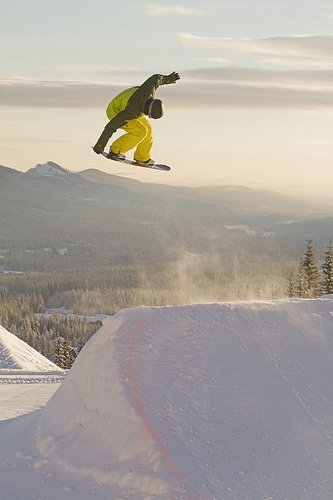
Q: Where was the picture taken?
A: It was taken at the forest.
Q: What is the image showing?
A: It is showing a forest.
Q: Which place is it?
A: It is a forest.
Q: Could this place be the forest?
A: Yes, it is the forest.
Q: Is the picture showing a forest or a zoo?
A: It is showing a forest.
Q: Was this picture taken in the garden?
A: No, the picture was taken in the forest.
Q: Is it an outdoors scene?
A: Yes, it is outdoors.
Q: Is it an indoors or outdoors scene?
A: It is outdoors.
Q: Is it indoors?
A: No, it is outdoors.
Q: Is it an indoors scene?
A: No, it is outdoors.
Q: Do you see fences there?
A: No, there are no fences.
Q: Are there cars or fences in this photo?
A: No, there are no fences or cars.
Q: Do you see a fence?
A: No, there are no fences.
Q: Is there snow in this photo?
A: Yes, there is snow.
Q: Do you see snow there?
A: Yes, there is snow.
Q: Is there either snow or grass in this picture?
A: Yes, there is snow.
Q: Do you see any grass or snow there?
A: Yes, there is snow.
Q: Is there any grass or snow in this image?
A: Yes, there is snow.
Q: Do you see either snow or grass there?
A: Yes, there is snow.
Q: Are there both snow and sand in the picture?
A: No, there is snow but no sand.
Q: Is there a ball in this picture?
A: No, there are no balls.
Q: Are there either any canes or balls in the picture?
A: No, there are no balls or canes.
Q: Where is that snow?
A: The snow is on the ground.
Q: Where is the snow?
A: The snow is on the ground.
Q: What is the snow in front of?
A: The snow is in front of the trees.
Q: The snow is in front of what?
A: The snow is in front of the trees.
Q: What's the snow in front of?
A: The snow is in front of the trees.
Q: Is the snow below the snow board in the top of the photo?
A: Yes, the snow is below the snow board.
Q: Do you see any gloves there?
A: Yes, there are gloves.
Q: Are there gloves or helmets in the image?
A: Yes, there are gloves.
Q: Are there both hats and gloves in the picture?
A: Yes, there are both gloves and a hat.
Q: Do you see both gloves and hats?
A: Yes, there are both gloves and a hat.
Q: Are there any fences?
A: No, there are no fences.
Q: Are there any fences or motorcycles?
A: No, there are no fences or motorcycles.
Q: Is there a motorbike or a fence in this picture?
A: No, there are no fences or motorcycles.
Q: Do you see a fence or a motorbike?
A: No, there are no fences or motorcycles.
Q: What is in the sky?
A: The clouds are in the sky.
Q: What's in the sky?
A: The clouds are in the sky.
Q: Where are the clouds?
A: The clouds are in the sky.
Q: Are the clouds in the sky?
A: Yes, the clouds are in the sky.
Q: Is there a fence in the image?
A: No, there are no fences.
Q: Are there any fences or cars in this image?
A: No, there are no fences or cars.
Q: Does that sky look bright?
A: Yes, the sky is bright.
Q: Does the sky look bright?
A: Yes, the sky is bright.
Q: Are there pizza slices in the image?
A: No, there are no pizza slices.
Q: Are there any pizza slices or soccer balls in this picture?
A: No, there are no pizza slices or soccer balls.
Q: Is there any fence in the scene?
A: No, there are no fences.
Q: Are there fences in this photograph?
A: No, there are no fences.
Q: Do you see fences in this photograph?
A: No, there are no fences.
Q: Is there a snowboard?
A: Yes, there is a snowboard.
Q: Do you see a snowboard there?
A: Yes, there is a snowboard.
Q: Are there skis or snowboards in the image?
A: Yes, there is a snowboard.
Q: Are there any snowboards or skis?
A: Yes, there is a snowboard.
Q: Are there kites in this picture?
A: No, there are no kites.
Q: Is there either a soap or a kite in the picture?
A: No, there are no kites or soaps.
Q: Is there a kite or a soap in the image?
A: No, there are no kites or soaps.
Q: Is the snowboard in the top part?
A: Yes, the snowboard is in the top of the image.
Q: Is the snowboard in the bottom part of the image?
A: No, the snowboard is in the top of the image.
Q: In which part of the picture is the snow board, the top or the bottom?
A: The snow board is in the top of the image.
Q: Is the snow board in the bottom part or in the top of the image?
A: The snow board is in the top of the image.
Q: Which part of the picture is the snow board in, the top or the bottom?
A: The snow board is in the top of the image.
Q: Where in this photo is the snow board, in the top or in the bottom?
A: The snow board is in the top of the image.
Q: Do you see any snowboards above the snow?
A: Yes, there is a snowboard above the snow.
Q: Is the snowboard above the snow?
A: Yes, the snowboard is above the snow.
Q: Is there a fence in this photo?
A: No, there are no fences.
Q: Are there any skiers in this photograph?
A: No, there are no skiers.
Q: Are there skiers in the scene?
A: No, there are no skiers.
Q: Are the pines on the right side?
A: Yes, the pines are on the right of the image.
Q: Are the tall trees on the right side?
A: Yes, the pines are on the right of the image.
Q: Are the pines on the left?
A: No, the pines are on the right of the image.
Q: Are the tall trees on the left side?
A: No, the pines are on the right of the image.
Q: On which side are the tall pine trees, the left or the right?
A: The pines are on the right of the image.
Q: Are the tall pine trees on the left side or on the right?
A: The pines are on the right of the image.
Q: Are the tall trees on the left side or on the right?
A: The pines are on the right of the image.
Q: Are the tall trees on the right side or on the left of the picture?
A: The pines are on the right of the image.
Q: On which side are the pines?
A: The pines are on the right of the image.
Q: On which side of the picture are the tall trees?
A: The pines are on the right of the image.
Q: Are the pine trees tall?
A: Yes, the pine trees are tall.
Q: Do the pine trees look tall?
A: Yes, the pine trees are tall.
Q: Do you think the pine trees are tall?
A: Yes, the pine trees are tall.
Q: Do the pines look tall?
A: Yes, the pines are tall.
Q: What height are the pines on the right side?
A: The pine trees are tall.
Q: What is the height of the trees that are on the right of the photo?
A: The pine trees are tall.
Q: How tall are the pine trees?
A: The pine trees are tall.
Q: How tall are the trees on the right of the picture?
A: The pine trees are tall.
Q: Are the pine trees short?
A: No, the pine trees are tall.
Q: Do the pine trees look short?
A: No, the pine trees are tall.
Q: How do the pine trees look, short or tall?
A: The pine trees are tall.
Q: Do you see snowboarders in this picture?
A: Yes, there is a snowboarder.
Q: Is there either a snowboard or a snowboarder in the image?
A: Yes, there is a snowboarder.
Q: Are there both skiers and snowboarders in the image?
A: No, there is a snowboarder but no skiers.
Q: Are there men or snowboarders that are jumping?
A: Yes, the snowboarder is jumping.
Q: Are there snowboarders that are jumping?
A: Yes, there is a snowboarder that is jumping.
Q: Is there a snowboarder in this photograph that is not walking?
A: Yes, there is a snowboarder that is jumping.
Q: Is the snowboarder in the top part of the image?
A: Yes, the snowboarder is in the top of the image.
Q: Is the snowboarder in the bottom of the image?
A: No, the snowboarder is in the top of the image.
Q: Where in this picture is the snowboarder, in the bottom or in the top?
A: The snowboarder is in the top of the image.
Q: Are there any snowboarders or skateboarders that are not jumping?
A: No, there is a snowboarder but he is jumping.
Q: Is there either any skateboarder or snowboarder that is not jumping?
A: No, there is a snowboarder but he is jumping.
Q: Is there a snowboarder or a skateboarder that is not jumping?
A: No, there is a snowboarder but he is jumping.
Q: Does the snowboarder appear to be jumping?
A: Yes, the snowboarder is jumping.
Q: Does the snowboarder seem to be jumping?
A: Yes, the snowboarder is jumping.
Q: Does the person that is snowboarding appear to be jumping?
A: Yes, the snowboarder is jumping.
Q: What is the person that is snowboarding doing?
A: The snowboarder is jumping.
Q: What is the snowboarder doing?
A: The snowboarder is jumping.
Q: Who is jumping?
A: The snowboarder is jumping.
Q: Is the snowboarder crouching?
A: No, the snowboarder is jumping.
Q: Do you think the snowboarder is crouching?
A: No, the snowboarder is jumping.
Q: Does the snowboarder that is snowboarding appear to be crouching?
A: No, the snowboarder is jumping.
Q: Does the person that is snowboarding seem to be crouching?
A: No, the snowboarder is jumping.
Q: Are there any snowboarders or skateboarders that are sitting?
A: No, there is a snowboarder but he is jumping.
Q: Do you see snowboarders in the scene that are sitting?
A: No, there is a snowboarder but he is jumping.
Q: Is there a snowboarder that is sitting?
A: No, there is a snowboarder but he is jumping.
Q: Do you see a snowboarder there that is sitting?
A: No, there is a snowboarder but he is jumping.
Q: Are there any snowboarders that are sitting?
A: No, there is a snowboarder but he is jumping.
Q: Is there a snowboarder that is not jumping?
A: No, there is a snowboarder but he is jumping.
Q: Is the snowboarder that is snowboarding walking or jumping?
A: The snowboarder is jumping.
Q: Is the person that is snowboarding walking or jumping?
A: The snowboarder is jumping.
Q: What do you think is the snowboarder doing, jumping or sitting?
A: The snowboarder is jumping.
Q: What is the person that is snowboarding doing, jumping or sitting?
A: The snowboarder is jumping.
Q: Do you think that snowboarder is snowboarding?
A: Yes, the snowboarder is snowboarding.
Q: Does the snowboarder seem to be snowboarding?
A: Yes, the snowboarder is snowboarding.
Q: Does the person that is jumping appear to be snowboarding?
A: Yes, the snowboarder is snowboarding.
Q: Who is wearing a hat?
A: The snowboarder is wearing a hat.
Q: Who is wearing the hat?
A: The snowboarder is wearing a hat.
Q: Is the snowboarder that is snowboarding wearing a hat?
A: Yes, the snowboarder is wearing a hat.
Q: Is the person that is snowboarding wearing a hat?
A: Yes, the snowboarder is wearing a hat.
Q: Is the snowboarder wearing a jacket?
A: No, the snowboarder is wearing a hat.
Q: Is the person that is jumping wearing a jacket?
A: No, the snowboarder is wearing a hat.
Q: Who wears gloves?
A: The snowboarder wears gloves.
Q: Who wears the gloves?
A: The snowboarder wears gloves.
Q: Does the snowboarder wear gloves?
A: Yes, the snowboarder wears gloves.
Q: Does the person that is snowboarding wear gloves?
A: Yes, the snowboarder wears gloves.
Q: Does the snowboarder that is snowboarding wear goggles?
A: No, the snowboarder wears gloves.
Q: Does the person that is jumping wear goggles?
A: No, the snowboarder wears gloves.